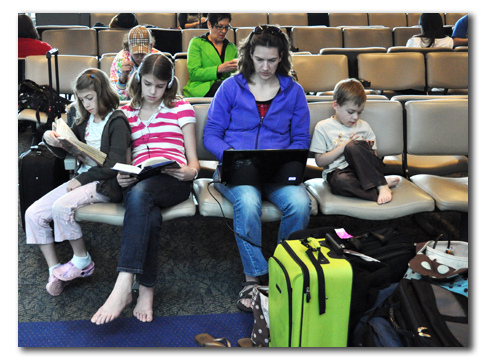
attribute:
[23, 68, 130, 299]
girl — reading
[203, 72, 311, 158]
jacket — purple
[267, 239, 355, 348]
suitcase — green, lime green, yellow green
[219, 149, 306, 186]
laptop — black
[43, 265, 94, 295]
sandals — pink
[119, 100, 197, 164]
shirt — stripes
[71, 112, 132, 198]
jacket — gray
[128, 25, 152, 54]
cap — a baseball cap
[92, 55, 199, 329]
girl — barefooted, bare feet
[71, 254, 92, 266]
socks — white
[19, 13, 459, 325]
people — waiting, inside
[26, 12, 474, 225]
chairs — brown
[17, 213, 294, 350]
carpet — blue, patterned, gray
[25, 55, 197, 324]
girls — reading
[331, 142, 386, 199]
pants — brown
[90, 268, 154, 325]
feet — bare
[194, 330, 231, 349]
flip flop sandal — brown